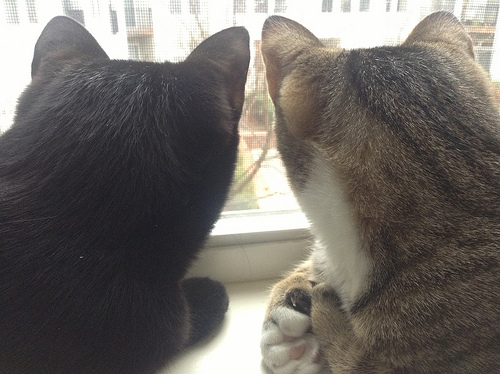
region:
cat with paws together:
[280, 277, 336, 370]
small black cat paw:
[172, 275, 237, 331]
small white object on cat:
[58, 227, 116, 276]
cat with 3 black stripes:
[315, 35, 476, 189]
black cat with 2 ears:
[26, 35, 259, 165]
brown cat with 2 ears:
[258, 3, 479, 90]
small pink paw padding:
[283, 343, 325, 370]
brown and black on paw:
[278, 272, 343, 327]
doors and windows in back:
[93, 3, 190, 58]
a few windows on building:
[305, 4, 429, 14]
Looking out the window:
[5, 10, 488, 351]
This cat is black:
[15, 75, 230, 314]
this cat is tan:
[340, 76, 495, 313]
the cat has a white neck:
[281, 177, 353, 249]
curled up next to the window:
[125, 220, 394, 371]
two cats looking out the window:
[8, 10, 496, 361]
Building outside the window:
[2, 0, 394, 105]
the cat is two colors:
[245, 64, 407, 369]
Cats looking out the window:
[9, 30, 478, 263]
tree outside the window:
[205, 40, 300, 219]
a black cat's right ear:
[185, 25, 250, 125]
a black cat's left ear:
[30, 16, 107, 79]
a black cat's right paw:
[184, 279, 230, 342]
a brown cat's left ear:
[261, 14, 327, 88]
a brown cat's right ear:
[407, 10, 476, 54]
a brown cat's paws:
[262, 268, 327, 371]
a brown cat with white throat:
[259, 11, 498, 371]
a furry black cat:
[0, 16, 251, 371]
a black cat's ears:
[28, 15, 250, 89]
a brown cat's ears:
[260, 10, 475, 91]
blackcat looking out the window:
[24, 15, 239, 225]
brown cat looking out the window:
[255, 14, 473, 291]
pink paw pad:
[281, 335, 308, 372]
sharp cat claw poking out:
[284, 290, 309, 332]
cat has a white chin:
[289, 144, 374, 320]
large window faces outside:
[134, 0, 491, 265]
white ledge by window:
[195, 277, 288, 370]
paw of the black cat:
[181, 278, 233, 363]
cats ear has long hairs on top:
[259, 12, 341, 120]